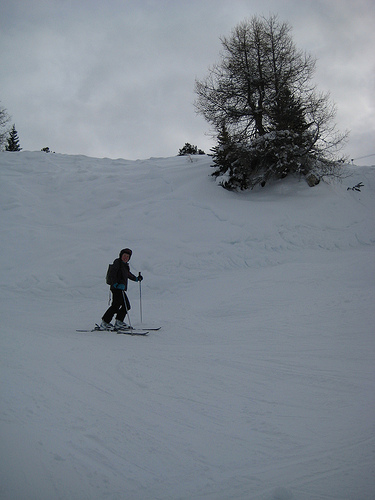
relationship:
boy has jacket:
[99, 248, 144, 333] [110, 258, 139, 292]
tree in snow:
[194, 14, 353, 190] [0, 150, 375, 500]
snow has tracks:
[0, 150, 375, 500] [5, 223, 374, 304]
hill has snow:
[0, 149, 375, 500] [0, 150, 375, 500]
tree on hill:
[194, 14, 353, 190] [0, 149, 375, 500]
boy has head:
[99, 248, 144, 333] [118, 248, 132, 264]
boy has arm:
[99, 248, 144, 333] [128, 271, 142, 283]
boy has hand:
[99, 248, 144, 333] [136, 274, 144, 284]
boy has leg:
[99, 248, 144, 333] [116, 290, 132, 330]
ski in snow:
[73, 327, 160, 337] [0, 150, 375, 500]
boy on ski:
[99, 248, 144, 333] [73, 327, 160, 337]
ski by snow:
[73, 327, 160, 337] [0, 150, 375, 500]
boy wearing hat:
[99, 248, 144, 333] [119, 248, 133, 263]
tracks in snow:
[5, 223, 374, 304] [0, 150, 375, 500]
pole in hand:
[137, 271, 144, 328] [136, 274, 144, 284]